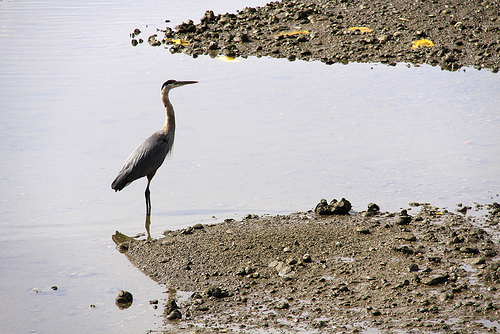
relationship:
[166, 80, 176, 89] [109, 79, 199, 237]
eye of bird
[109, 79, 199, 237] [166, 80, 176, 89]
bird has an eye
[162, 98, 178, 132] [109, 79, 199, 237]
neck of bird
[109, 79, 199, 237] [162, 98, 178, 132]
bird has neck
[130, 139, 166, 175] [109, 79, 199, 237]
wing of bird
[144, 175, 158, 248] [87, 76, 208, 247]
legs of crane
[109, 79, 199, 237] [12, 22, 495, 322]
bird in water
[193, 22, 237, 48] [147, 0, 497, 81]
rocks in dirt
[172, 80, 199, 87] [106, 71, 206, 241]
beak of bird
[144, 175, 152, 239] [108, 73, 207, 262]
legs of crane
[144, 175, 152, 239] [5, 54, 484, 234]
legs in water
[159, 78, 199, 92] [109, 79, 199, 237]
head belonging to bird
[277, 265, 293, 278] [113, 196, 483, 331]
stone lying in dirt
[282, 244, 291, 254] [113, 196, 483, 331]
stone lying in dirt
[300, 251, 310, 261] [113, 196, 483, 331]
stone lying in dirt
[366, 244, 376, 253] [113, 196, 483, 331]
stone lying in dirt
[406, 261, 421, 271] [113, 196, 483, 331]
stone lying in dirt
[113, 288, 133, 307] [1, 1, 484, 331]
rock lying in water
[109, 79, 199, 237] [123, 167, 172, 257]
bird with legs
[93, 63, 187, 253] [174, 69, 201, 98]
bird with beak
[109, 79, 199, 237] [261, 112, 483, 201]
bird standing by water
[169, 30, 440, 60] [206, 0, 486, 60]
spots in dirt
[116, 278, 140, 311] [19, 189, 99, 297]
rock laying in water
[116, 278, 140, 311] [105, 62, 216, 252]
rock by bird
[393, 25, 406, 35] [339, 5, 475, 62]
rock on ground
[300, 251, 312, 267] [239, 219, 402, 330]
rock on ground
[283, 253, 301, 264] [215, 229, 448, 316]
rock on ground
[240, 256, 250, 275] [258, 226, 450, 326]
rock on ground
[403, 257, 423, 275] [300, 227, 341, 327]
rock on ground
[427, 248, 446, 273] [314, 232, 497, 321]
rock on ground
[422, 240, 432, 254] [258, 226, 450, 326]
rock on ground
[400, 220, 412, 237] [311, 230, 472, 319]
rock on ground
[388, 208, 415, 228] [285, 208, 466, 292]
rock on ground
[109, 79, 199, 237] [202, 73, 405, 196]
bird standing near water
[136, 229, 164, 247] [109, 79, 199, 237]
feet of bird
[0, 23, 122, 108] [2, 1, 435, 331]
ripples in water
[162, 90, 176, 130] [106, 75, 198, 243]
neck of bird